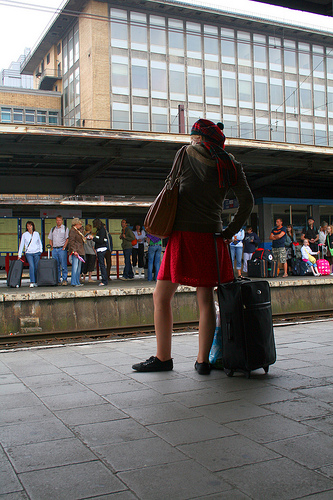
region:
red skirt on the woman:
[151, 229, 237, 286]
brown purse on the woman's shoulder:
[139, 144, 188, 239]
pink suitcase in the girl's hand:
[315, 241, 331, 275]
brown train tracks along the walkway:
[0, 308, 332, 349]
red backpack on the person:
[121, 225, 139, 246]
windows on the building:
[107, 4, 332, 148]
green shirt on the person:
[146, 234, 163, 247]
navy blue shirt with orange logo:
[269, 225, 287, 247]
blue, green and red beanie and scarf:
[187, 114, 239, 188]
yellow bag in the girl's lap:
[306, 248, 316, 263]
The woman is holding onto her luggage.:
[120, 112, 293, 387]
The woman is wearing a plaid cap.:
[122, 115, 283, 389]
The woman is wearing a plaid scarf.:
[131, 116, 280, 381]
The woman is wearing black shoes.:
[121, 111, 281, 385]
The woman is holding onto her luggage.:
[3, 217, 40, 286]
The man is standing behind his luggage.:
[34, 212, 69, 287]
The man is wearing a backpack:
[114, 218, 141, 282]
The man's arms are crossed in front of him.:
[268, 216, 290, 280]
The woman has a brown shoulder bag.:
[118, 113, 284, 388]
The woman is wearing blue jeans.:
[5, 217, 47, 293]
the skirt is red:
[151, 230, 252, 281]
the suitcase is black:
[203, 226, 285, 373]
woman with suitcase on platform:
[122, 105, 280, 376]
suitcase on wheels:
[211, 232, 283, 376]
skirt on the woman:
[153, 229, 235, 288]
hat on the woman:
[186, 116, 228, 140]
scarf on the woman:
[196, 141, 238, 185]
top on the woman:
[179, 147, 254, 236]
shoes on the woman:
[133, 354, 215, 375]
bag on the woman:
[143, 148, 182, 239]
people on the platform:
[4, 213, 330, 271]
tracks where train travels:
[3, 297, 327, 330]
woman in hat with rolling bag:
[128, 112, 291, 388]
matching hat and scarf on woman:
[186, 114, 242, 198]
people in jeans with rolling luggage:
[5, 210, 73, 293]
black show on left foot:
[122, 349, 184, 380]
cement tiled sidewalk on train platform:
[24, 352, 136, 468]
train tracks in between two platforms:
[5, 285, 85, 378]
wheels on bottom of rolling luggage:
[218, 353, 277, 396]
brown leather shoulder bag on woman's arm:
[137, 137, 189, 249]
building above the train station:
[47, 0, 277, 352]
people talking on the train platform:
[62, 212, 117, 300]